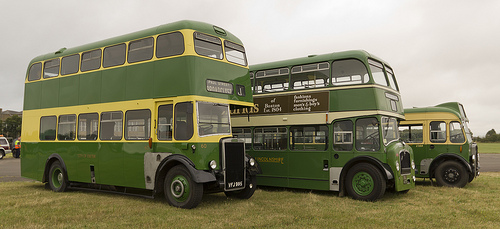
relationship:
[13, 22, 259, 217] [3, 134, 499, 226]
bus in field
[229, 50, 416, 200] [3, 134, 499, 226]
bus in field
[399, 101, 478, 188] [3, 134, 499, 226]
bus in field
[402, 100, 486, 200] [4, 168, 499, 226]
bus in field